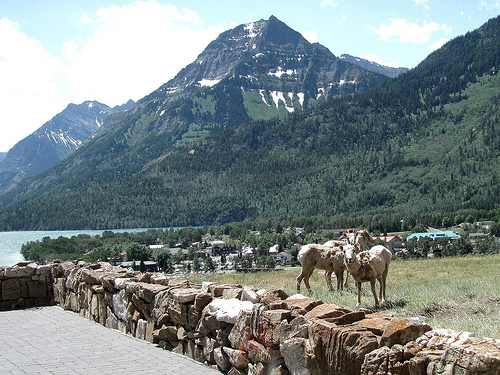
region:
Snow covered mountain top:
[153, 14, 377, 131]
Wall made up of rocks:
[64, 257, 266, 354]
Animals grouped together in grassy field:
[290, 213, 405, 306]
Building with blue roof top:
[404, 225, 464, 259]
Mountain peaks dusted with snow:
[11, 12, 387, 188]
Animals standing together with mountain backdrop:
[202, 37, 401, 319]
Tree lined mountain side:
[252, 136, 453, 238]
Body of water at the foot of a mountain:
[4, 66, 197, 278]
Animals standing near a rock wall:
[264, 210, 403, 371]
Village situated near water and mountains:
[106, 180, 491, 270]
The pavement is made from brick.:
[25, 334, 87, 371]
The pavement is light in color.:
[10, 327, 87, 373]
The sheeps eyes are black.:
[341, 242, 358, 264]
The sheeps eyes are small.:
[339, 243, 358, 265]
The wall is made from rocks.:
[156, 290, 243, 351]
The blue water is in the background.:
[3, 233, 20, 255]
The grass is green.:
[427, 263, 477, 294]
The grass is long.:
[429, 268, 481, 293]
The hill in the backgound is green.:
[271, 131, 363, 191]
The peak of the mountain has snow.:
[221, 12, 296, 47]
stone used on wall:
[379, 313, 426, 344]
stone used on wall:
[306, 321, 368, 373]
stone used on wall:
[350, 314, 385, 331]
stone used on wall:
[242, 340, 271, 361]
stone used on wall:
[248, 304, 278, 343]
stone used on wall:
[218, 345, 244, 367]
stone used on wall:
[201, 338, 216, 360]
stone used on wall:
[206, 300, 248, 324]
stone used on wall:
[133, 318, 148, 339]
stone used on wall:
[141, 320, 153, 343]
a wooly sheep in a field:
[342, 243, 401, 303]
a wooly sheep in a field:
[298, 233, 354, 292]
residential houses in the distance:
[406, 230, 459, 243]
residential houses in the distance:
[192, 237, 227, 250]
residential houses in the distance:
[146, 233, 483, 263]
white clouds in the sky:
[71, 3, 203, 77]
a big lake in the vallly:
[0, 226, 217, 273]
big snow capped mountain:
[0, 15, 497, 142]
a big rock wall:
[48, 260, 498, 372]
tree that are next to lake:
[20, 231, 151, 265]